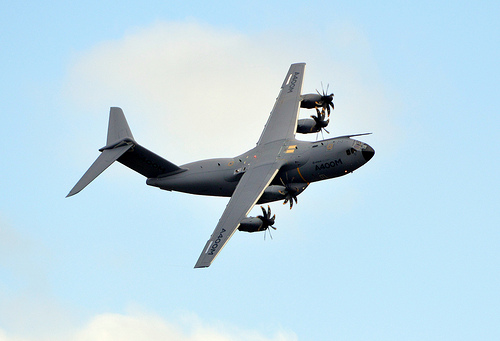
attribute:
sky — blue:
[377, 1, 498, 339]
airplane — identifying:
[107, 67, 422, 270]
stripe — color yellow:
[292, 164, 315, 186]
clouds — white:
[64, 19, 373, 152]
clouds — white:
[114, 23, 227, 93]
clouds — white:
[50, 62, 111, 124]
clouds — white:
[106, 207, 175, 276]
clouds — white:
[338, 56, 387, 106]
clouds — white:
[97, 311, 234, 337]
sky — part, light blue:
[377, 28, 479, 338]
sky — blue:
[375, 94, 471, 221]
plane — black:
[65, 62, 375, 268]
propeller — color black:
[316, 83, 335, 117]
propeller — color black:
[308, 109, 330, 138]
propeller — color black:
[279, 179, 300, 210]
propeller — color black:
[256, 202, 277, 236]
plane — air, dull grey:
[57, 43, 401, 287]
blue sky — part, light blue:
[415, 217, 476, 297]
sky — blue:
[288, 257, 340, 294]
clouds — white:
[91, 26, 340, 166]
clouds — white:
[57, 306, 247, 339]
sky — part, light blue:
[288, 253, 460, 340]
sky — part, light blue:
[333, 209, 429, 311]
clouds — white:
[45, 8, 402, 224]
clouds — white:
[1, 291, 311, 339]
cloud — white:
[75, 310, 240, 339]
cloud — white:
[66, 22, 346, 152]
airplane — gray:
[53, 42, 380, 294]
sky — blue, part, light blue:
[2, 1, 495, 335]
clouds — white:
[0, 293, 341, 339]